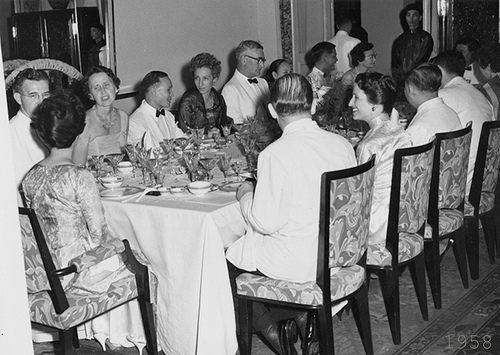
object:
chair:
[231, 151, 378, 314]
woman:
[344, 68, 414, 244]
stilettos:
[323, 300, 355, 327]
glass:
[194, 152, 223, 182]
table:
[96, 198, 242, 226]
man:
[122, 68, 190, 155]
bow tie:
[152, 102, 169, 117]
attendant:
[384, 2, 452, 78]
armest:
[35, 240, 152, 271]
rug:
[393, 274, 500, 354]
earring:
[369, 103, 376, 113]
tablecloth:
[97, 202, 240, 354]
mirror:
[0, 0, 79, 56]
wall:
[116, 0, 226, 49]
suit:
[218, 69, 273, 126]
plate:
[217, 180, 241, 193]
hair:
[352, 69, 398, 116]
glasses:
[241, 54, 272, 63]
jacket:
[223, 117, 355, 284]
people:
[0, 3, 500, 299]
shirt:
[123, 97, 192, 155]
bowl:
[182, 178, 215, 197]